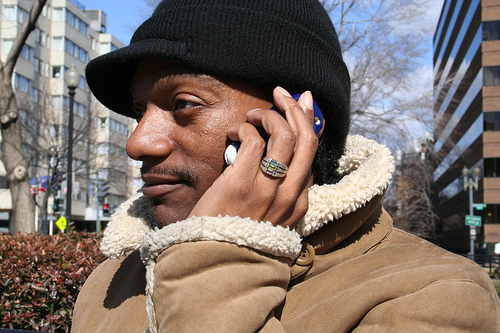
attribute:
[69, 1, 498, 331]
man — light brown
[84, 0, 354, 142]
cap — black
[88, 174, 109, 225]
lights — traffic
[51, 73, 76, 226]
post — black, lamp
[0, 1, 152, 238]
building — large, background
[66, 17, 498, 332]
man jacket — brown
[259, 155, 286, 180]
ring — man's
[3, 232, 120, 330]
shrubs — red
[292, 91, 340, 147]
cellphone — blue, white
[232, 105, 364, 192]
phone — blue, white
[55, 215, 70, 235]
sign — yellow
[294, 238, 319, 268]
button — brown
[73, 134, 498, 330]
coat — sheep wool, brown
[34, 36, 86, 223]
streetlamp — tall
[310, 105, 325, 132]
cellphone — blue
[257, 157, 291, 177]
ring — large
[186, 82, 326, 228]
hand — man's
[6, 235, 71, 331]
bush — red, green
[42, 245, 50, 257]
leaves — red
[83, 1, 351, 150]
hat — black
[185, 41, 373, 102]
hat — black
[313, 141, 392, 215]
wool — sheep